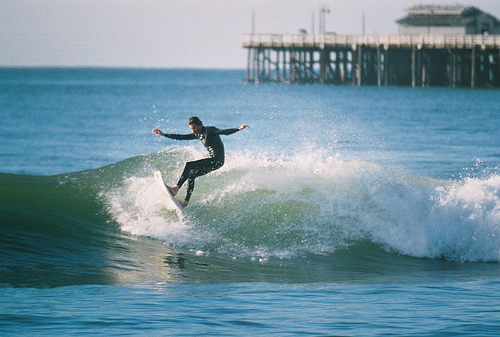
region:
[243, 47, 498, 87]
a wooden pier in the distance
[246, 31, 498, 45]
a fence on a pier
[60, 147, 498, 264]
a big wave on the ocean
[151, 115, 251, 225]
a man surfing on a surfboard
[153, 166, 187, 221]
a white surfboard on the water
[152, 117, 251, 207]
a man surfing a wave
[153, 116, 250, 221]
man keeping his balance on a surfboard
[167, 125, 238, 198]
man wearing a black wet suit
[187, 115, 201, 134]
man with brown hair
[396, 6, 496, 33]
a metal structure on a pier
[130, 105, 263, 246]
A young man surfing a wave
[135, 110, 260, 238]
A young man surfing a wave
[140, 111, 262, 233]
A young man surfing a wave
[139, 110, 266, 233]
A young man surfing a wave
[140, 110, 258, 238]
A young man surfing a wave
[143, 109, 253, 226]
A young man surfing a wave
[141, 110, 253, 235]
A young man surfing a wave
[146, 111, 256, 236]
A young man surfing a wave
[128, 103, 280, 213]
This is a person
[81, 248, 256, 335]
This is a mass of water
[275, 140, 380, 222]
This is a mass of water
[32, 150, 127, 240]
This is a mass of water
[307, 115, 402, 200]
This is a mass of water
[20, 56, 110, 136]
This is a mass of water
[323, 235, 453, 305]
This is a mass of water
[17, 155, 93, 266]
This is a mass of water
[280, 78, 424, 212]
This is a mass of water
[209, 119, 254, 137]
arm of a person on a surfboard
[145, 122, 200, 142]
arm of a person on a surfboard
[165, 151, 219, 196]
leg of a person on a surfboard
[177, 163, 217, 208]
leg of a person on a surfboard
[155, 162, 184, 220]
white surfboard in the water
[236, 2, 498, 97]
wooden pier with a building on it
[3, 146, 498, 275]
small wave in the water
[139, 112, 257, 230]
person riding a white surfboard on a wave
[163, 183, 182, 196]
bare foot of a person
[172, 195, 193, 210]
bare foot of a person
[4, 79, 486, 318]
water man is surfing in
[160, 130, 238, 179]
wetsuit on the man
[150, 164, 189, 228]
board man surfs on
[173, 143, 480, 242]
white water near surfer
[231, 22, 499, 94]
deck extending into water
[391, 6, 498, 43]
building on top of deck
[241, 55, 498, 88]
supportive structure of deck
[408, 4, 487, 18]
roof of building on deck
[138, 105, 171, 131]
splashes of water near surfer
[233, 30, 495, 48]
fence around the deck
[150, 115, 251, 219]
a man on a surfboard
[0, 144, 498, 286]
a large wave rolling in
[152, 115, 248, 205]
a man wearing a black wet suit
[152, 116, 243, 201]
a man is surfing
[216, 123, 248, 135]
arm of a man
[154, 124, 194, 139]
arm of a man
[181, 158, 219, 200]
leg of a man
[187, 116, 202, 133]
head of a man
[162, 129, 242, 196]
wet suit is black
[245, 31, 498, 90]
pier in the background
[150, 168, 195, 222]
the board is white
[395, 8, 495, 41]
building on the pier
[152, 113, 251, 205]
surfer wearing black wet suit